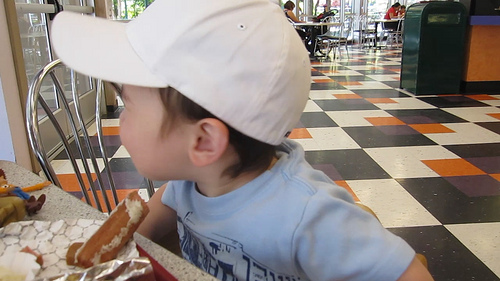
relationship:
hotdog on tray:
[71, 191, 151, 270] [135, 238, 174, 279]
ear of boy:
[190, 112, 229, 166] [119, 0, 437, 281]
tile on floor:
[342, 126, 438, 147] [332, 97, 494, 177]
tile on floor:
[421, 157, 485, 174] [332, 97, 494, 177]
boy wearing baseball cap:
[112, 0, 439, 280] [49, 0, 312, 146]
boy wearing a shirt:
[119, 0, 437, 281] [170, 181, 417, 279]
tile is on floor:
[350, 100, 476, 208] [320, 55, 477, 255]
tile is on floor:
[375, 120, 420, 144] [25, 43, 499, 278]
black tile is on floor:
[338, 124, 440, 149] [309, 89, 496, 273]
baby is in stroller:
[310, 0, 335, 22] [302, 4, 338, 55]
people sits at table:
[384, 2, 400, 20] [366, 17, 403, 48]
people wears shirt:
[384, 2, 400, 20] [384, 5, 400, 16]